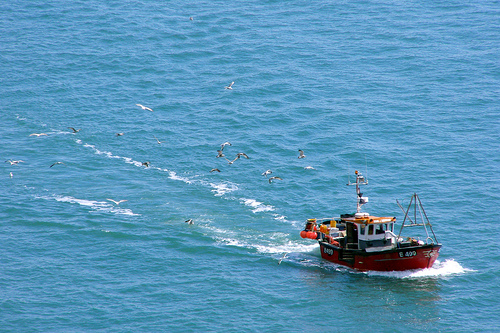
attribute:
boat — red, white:
[298, 167, 445, 278]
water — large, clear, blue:
[2, 3, 494, 330]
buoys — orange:
[182, 137, 354, 215]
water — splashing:
[274, 54, 433, 109]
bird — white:
[133, 98, 155, 117]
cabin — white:
[343, 201, 393, 238]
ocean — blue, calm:
[2, 0, 499, 332]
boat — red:
[279, 168, 469, 288]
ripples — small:
[83, 139, 311, 238]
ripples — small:
[45, 184, 295, 280]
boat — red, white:
[291, 164, 446, 290]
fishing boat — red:
[285, 180, 426, 284]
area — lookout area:
[346, 166, 371, 186]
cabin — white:
[340, 210, 398, 250]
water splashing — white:
[372, 253, 466, 277]